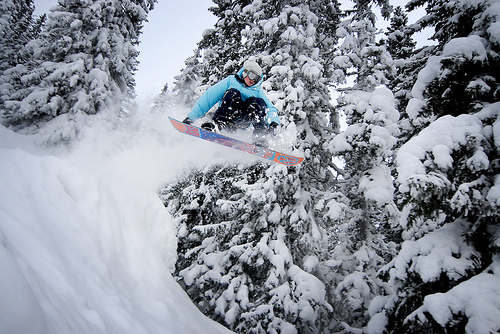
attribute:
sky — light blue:
[31, 0, 442, 109]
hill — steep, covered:
[1, 123, 236, 333]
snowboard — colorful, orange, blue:
[167, 114, 304, 168]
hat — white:
[241, 60, 265, 78]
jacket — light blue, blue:
[187, 68, 282, 133]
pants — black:
[214, 88, 269, 145]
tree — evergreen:
[383, 1, 498, 333]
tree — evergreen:
[328, 0, 391, 332]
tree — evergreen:
[372, 4, 428, 126]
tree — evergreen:
[160, 0, 332, 333]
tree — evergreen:
[1, 1, 159, 149]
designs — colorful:
[166, 115, 303, 167]